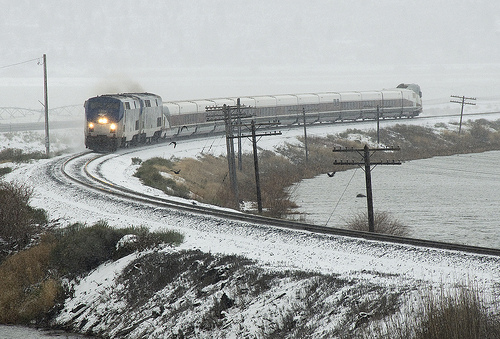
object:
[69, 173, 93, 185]
metal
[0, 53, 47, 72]
wire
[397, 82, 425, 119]
caboose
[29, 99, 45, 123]
sprinkler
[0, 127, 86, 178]
field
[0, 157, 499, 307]
snow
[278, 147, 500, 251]
lake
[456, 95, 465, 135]
pole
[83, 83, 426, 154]
train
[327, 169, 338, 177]
bird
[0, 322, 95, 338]
water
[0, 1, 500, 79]
sky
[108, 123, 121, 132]
locomotive headlights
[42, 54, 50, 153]
pole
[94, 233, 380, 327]
snow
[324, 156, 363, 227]
power lines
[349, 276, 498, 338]
weeds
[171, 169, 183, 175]
bird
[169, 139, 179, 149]
bird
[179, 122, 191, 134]
bird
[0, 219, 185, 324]
grass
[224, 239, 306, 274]
snow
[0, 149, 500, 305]
ground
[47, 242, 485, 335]
hill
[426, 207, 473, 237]
snow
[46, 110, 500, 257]
tracks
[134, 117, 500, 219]
embankment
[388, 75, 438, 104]
spoiler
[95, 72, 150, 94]
smoke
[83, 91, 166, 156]
engine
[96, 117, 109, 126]
lights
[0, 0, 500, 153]
fog